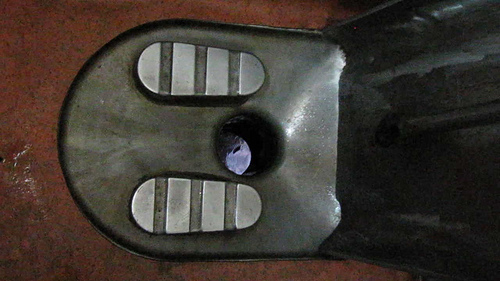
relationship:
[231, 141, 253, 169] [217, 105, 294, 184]
water from borrow of hole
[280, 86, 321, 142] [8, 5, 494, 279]
light on ground